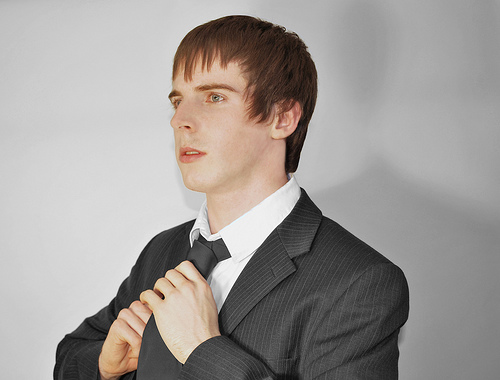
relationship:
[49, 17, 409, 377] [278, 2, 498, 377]
man casts shadow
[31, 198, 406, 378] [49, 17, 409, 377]
jacket on man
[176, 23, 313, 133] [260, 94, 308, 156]
hair coverintg ear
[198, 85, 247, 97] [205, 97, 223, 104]
eyebrow over eye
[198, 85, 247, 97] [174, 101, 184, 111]
eyebrow over eye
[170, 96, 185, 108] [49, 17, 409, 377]
eye of man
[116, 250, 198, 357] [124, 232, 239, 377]
fingers around tie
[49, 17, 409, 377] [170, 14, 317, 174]
man has hair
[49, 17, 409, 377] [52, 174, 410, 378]
man wearing suit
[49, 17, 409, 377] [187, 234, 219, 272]
man tying h tie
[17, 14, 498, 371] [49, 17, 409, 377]
wall behind man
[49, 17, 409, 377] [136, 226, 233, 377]
man adjusting tie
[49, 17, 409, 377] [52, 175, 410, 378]
man in clothing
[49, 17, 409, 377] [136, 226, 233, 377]
man tying tie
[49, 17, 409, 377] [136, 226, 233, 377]
man fixing tie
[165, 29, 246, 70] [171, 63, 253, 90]
bangs laying on forehead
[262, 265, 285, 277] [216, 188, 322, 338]
button hole in lapel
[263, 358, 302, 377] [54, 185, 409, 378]
pocket in suit coat